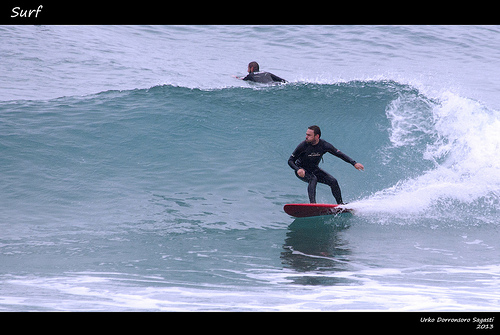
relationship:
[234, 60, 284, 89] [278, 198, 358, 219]
guy laying on board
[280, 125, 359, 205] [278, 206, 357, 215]
man on surfboard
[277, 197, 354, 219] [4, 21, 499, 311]
surfboard top of water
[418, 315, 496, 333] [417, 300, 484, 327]
logo in corner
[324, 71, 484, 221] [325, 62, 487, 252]
foam top of wave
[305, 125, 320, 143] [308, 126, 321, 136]
man head with wet hair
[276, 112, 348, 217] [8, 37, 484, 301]
man in ocean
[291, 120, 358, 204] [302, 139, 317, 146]
guy has beard